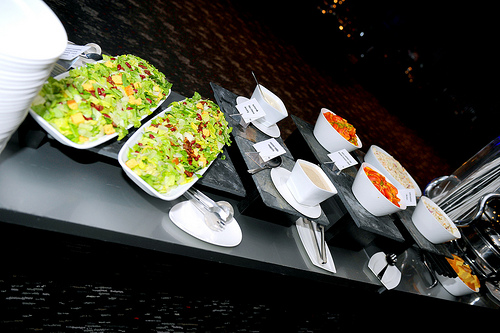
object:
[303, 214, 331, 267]
tongs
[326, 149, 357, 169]
paper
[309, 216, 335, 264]
napkins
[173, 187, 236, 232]
tongs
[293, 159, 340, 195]
cup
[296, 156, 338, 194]
coffee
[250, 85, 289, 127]
bowl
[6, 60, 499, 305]
table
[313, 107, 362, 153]
bowls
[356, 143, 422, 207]
bowls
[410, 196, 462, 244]
bowls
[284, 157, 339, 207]
bowls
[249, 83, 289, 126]
bowls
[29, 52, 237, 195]
food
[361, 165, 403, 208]
food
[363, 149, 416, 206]
food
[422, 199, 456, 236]
food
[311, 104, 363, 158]
bowl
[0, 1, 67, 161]
plates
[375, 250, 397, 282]
spoon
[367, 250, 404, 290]
plate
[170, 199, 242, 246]
plate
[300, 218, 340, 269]
plate